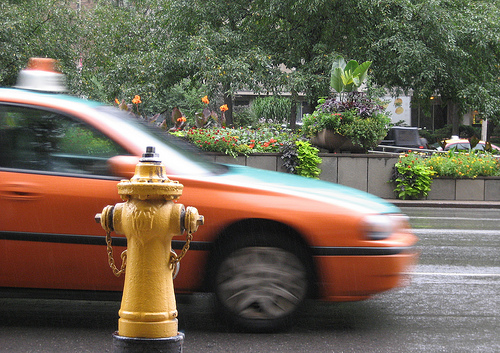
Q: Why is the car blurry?
A: Camera was set at a low shutter speed.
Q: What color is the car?
A: Orange.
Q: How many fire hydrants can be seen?
A: One.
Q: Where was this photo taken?
A: A street.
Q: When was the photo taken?
A: Daytime.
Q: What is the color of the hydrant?
A: Yellow.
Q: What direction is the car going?
A: Right.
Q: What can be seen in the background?
A: Plants.